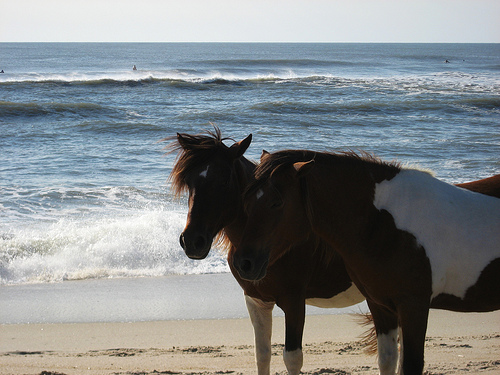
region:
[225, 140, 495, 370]
this is a horse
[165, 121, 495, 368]
this is a horse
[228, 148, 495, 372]
this is a white and brown horse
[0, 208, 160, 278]
this is a body of water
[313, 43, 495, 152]
this is a body of water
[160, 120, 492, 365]
one horse standing slightly ahead of the other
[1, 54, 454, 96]
heads bobbing beyond the wave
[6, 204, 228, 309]
water splashing in front of the sand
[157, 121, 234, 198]
brown hair over eye and ears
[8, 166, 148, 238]
water swirling behind wave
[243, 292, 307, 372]
white leg next to brown and white leg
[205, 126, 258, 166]
eat pointing up at a slant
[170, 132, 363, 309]
white underbelly on brown horse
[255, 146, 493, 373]
brown and white horse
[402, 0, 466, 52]
white clouds in blue sky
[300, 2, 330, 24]
white clouds in blue sky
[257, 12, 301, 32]
white clouds in blue sky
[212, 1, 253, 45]
white clouds in blue sky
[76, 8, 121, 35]
white clouds in blue sky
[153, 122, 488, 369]
two horses on a beach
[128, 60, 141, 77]
a person in the water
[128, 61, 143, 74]
a person swimming in the ocean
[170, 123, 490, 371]
two brown and white horses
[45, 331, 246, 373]
tracks in the sand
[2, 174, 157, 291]
white waves in the water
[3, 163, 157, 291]
white waves in the ocean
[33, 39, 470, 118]
a large body of water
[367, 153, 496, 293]
a white spot on a horse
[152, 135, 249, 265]
brown horse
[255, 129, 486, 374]
brown and white horse on beach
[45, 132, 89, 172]
white and blue ocean waves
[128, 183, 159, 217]
white and blue ocean waves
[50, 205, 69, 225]
white and blue ocean waves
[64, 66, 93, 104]
white and blue ocean waves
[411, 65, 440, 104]
white and blue ocean waves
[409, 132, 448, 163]
white and blue ocean waves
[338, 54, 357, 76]
white and blue ocean waves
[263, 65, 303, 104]
white and blue ocean waves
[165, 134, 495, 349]
two horses on beach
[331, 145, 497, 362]
brown and white horse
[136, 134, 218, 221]
horse has brown mane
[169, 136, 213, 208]
horse has brown ears